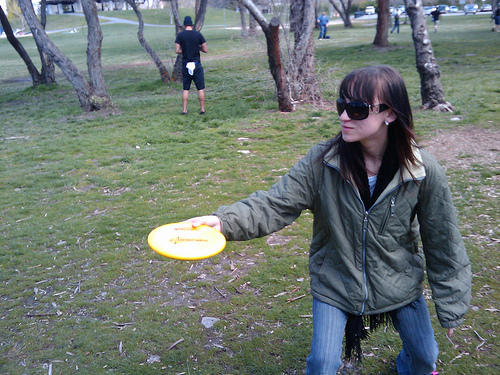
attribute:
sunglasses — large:
[332, 96, 371, 118]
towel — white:
[186, 62, 196, 75]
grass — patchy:
[69, 97, 356, 319]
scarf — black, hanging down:
[345, 148, 394, 225]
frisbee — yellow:
[141, 190, 240, 275]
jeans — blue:
[292, 298, 450, 349]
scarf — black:
[345, 143, 405, 363]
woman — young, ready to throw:
[145, 57, 476, 371]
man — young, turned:
[168, 14, 213, 119]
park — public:
[16, 10, 479, 343]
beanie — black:
[179, 51, 190, 62]